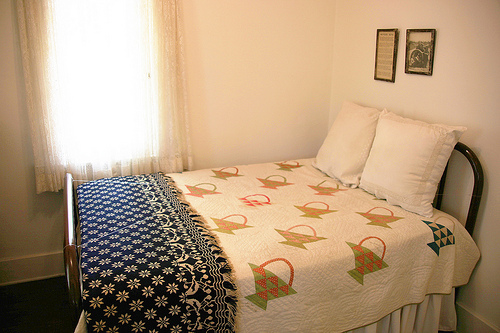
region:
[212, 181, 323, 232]
Quilt with basket pattern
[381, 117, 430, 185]
White bed pillow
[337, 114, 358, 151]
Part of white bed pillow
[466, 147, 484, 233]
Part of iron bed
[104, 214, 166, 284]
Daisey pattern bed blanket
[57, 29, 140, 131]
Sunlight streaming in window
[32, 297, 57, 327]
Part of bedroom floor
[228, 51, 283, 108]
Part of bedroom wall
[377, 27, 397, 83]
Picture on Bedroom wall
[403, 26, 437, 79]
Picture on bedroom wall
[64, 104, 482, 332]
large bed by the window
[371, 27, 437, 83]
old pictures hanging on the wall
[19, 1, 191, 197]
white curtains over the window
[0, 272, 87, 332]
blue carpet on the floor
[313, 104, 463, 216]
two white pillows on the bed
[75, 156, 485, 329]
blanket with several designs covering the bed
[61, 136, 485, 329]
bed with a wooden frame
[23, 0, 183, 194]
window with sunlight shining through the curtains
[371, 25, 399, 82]
old picture of a document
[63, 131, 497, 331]
large bed in the white bedroom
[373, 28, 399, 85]
framed paper covered with printed words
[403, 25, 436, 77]
framed black and white picture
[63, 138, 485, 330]
brass bed frame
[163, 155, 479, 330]
multi-colored basket themed bed quilt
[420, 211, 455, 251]
blue and yellow quilted basket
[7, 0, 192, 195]
white gauzy curtain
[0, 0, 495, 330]
white painted walls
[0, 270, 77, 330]
dark blue bedroom carpeting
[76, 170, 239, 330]
blue and white woven throw blanket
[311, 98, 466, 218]
two white pillows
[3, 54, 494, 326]
a bed in a house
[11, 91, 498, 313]
a bed in a room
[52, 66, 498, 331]
a bed with a metal post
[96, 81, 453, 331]
a bed with two pillows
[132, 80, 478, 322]
a bed with two white pillows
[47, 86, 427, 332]
a bed with a quilt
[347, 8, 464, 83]
pictures on the wall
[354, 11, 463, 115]
two pictures on a wall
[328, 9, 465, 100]
framed pictures on the wall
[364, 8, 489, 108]
two framed picture on the wall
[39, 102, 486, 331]
bed that is made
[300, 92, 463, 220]
two pillows propped up on the bed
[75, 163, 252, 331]
white and blue blanket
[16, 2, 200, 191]
curtains covering the window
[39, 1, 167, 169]
light shining through the curtains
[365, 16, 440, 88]
two frames on the wall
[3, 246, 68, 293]
white trim on the bottom of the wall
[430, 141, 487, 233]
iron headboard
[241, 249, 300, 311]
drawing on the bedspread